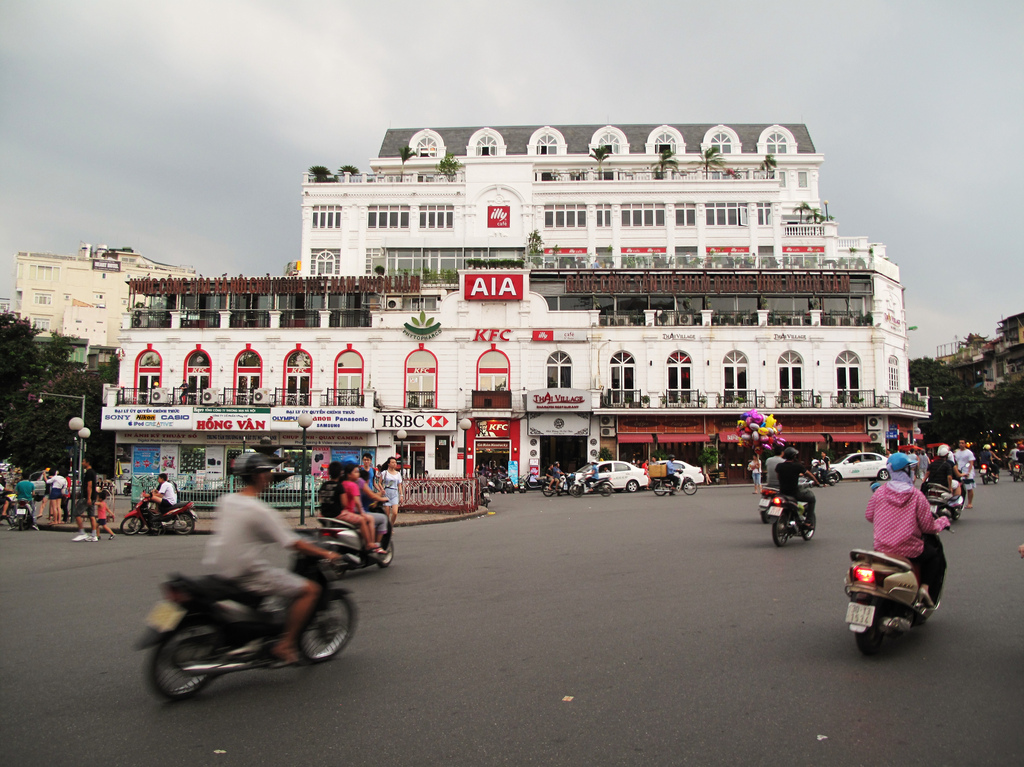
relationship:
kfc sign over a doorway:
[476, 419, 511, 437] [466, 417, 520, 482]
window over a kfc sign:
[462, 348, 510, 402] [477, 408, 523, 439]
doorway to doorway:
[466, 419, 521, 483] [466, 417, 520, 482]